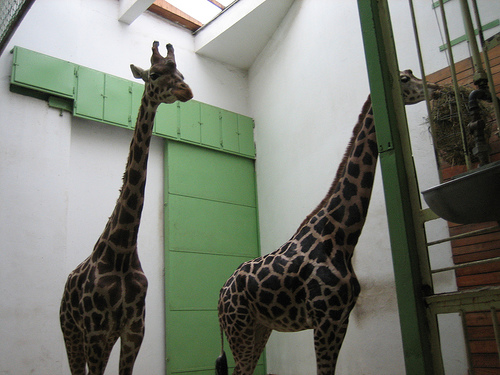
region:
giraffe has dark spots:
[286, 267, 318, 312]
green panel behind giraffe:
[202, 209, 240, 238]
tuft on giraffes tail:
[213, 348, 235, 365]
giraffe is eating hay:
[435, 94, 472, 128]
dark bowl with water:
[413, 170, 490, 225]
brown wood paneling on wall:
[476, 261, 497, 316]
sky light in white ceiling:
[176, 0, 234, 42]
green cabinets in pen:
[63, 63, 285, 153]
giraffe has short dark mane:
[125, 155, 150, 206]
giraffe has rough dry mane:
[299, 195, 382, 226]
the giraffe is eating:
[252, 49, 459, 222]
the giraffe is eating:
[341, 51, 491, 193]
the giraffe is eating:
[328, 49, 457, 149]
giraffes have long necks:
[89, 87, 216, 256]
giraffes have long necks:
[115, 86, 450, 371]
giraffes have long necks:
[304, 79, 450, 279]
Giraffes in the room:
[81, 53, 431, 370]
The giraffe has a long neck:
[98, 101, 163, 251]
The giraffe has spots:
[262, 265, 314, 302]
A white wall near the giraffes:
[284, 93, 330, 185]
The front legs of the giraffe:
[306, 328, 355, 371]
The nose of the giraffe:
[178, 78, 192, 92]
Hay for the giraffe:
[431, 83, 489, 155]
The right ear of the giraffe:
[129, 66, 150, 80]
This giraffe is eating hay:
[213, 68, 439, 372]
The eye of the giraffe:
[146, 70, 161, 80]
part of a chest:
[316, 237, 368, 323]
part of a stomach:
[258, 254, 302, 302]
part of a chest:
[333, 274, 368, 294]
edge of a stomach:
[276, 307, 300, 320]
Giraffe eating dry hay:
[212, 68, 439, 374]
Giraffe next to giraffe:
[55, 38, 199, 373]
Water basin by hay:
[421, 150, 498, 231]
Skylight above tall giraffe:
[129, 0, 245, 43]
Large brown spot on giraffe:
[129, 138, 148, 165]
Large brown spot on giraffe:
[299, 228, 319, 253]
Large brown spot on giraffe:
[337, 171, 359, 202]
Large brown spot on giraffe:
[345, 156, 363, 179]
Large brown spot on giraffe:
[305, 234, 335, 266]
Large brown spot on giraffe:
[343, 200, 363, 231]